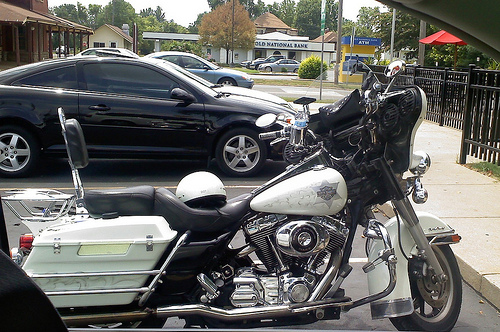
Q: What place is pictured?
A: It is a parking lot.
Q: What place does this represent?
A: It represents the parking lot.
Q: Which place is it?
A: It is a parking lot.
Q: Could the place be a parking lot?
A: Yes, it is a parking lot.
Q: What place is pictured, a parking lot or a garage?
A: It is a parking lot.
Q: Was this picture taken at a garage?
A: No, the picture was taken in a parking lot.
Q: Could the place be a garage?
A: No, it is a parking lot.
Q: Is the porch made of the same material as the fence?
A: No, the porch is made of wood and the fence is made of metal.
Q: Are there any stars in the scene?
A: Yes, there is a star.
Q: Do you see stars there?
A: Yes, there is a star.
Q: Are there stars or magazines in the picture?
A: Yes, there is a star.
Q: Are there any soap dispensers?
A: No, there are no soap dispensers.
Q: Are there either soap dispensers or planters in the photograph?
A: No, there are no soap dispensers or planters.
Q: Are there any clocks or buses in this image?
A: No, there are no buses or clocks.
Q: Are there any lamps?
A: No, there are no lamps.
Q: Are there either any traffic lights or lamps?
A: No, there are no lamps or traffic lights.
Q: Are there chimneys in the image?
A: No, there are no chimneys.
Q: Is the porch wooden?
A: Yes, the porch is wooden.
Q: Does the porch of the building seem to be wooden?
A: Yes, the porch is wooden.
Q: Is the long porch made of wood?
A: Yes, the porch is made of wood.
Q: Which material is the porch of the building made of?
A: The porch is made of wood.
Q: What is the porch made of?
A: The porch is made of wood.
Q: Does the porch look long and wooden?
A: Yes, the porch is long and wooden.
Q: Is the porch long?
A: Yes, the porch is long.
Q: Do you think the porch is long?
A: Yes, the porch is long.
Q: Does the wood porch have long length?
A: Yes, the porch is long.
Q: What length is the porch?
A: The porch is long.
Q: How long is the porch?
A: The porch is long.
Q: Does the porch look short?
A: No, the porch is long.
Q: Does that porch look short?
A: No, the porch is long.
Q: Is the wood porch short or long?
A: The porch is long.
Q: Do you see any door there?
A: Yes, there is a door.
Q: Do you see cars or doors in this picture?
A: Yes, there is a door.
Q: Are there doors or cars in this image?
A: Yes, there is a door.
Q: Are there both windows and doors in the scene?
A: Yes, there are both a door and a window.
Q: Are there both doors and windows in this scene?
A: Yes, there are both a door and a window.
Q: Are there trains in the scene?
A: No, there are no trains.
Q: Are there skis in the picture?
A: No, there are no skis.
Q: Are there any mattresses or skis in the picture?
A: No, there are no skis or mattresses.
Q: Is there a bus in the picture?
A: No, there are no buses.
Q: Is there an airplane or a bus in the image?
A: No, there are no buses or airplanes.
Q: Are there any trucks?
A: No, there are no trucks.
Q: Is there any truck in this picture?
A: No, there are no trucks.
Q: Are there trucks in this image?
A: No, there are no trucks.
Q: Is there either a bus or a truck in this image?
A: No, there are no trucks or buses.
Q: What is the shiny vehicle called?
A: The vehicle is a car.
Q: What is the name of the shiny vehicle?
A: The vehicle is a car.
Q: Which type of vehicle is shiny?
A: The vehicle is a car.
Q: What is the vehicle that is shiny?
A: The vehicle is a car.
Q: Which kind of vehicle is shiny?
A: The vehicle is a car.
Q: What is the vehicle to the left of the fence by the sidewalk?
A: The vehicle is a car.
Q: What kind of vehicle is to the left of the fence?
A: The vehicle is a car.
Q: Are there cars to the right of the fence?
A: No, the car is to the left of the fence.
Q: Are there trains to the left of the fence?
A: No, there is a car to the left of the fence.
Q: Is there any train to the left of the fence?
A: No, there is a car to the left of the fence.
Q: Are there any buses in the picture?
A: No, there are no buses.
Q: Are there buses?
A: No, there are no buses.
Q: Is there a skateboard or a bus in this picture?
A: No, there are no buses or skateboards.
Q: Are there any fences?
A: Yes, there is a fence.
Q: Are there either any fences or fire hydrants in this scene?
A: Yes, there is a fence.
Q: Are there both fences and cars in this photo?
A: Yes, there are both a fence and a car.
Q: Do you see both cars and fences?
A: Yes, there are both a fence and a car.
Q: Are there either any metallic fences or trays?
A: Yes, there is a metal fence.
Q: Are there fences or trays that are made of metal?
A: Yes, the fence is made of metal.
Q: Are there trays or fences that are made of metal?
A: Yes, the fence is made of metal.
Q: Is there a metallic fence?
A: Yes, there is a metal fence.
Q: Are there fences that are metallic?
A: Yes, there is a fence that is metallic.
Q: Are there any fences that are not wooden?
A: Yes, there is a metallic fence.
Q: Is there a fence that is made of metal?
A: Yes, there is a fence that is made of metal.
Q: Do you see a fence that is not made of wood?
A: Yes, there is a fence that is made of metal.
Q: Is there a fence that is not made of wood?
A: Yes, there is a fence that is made of metal.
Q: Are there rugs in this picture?
A: No, there are no rugs.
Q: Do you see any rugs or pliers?
A: No, there are no rugs or pliers.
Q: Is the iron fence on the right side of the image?
A: Yes, the fence is on the right of the image.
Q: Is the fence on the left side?
A: No, the fence is on the right of the image.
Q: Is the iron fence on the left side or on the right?
A: The fence is on the right of the image.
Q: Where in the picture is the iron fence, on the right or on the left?
A: The fence is on the right of the image.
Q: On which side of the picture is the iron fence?
A: The fence is on the right of the image.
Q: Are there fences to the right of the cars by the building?
A: Yes, there is a fence to the right of the cars.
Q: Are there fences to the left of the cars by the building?
A: No, the fence is to the right of the cars.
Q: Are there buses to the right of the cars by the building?
A: No, there is a fence to the right of the cars.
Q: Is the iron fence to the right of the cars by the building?
A: Yes, the fence is to the right of the cars.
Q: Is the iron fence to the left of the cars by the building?
A: No, the fence is to the right of the cars.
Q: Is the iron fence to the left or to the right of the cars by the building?
A: The fence is to the right of the cars.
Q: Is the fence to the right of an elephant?
A: No, the fence is to the right of the car.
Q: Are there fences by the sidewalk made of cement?
A: Yes, there is a fence by the sidewalk.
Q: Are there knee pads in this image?
A: No, there are no knee pads.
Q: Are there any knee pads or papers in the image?
A: No, there are no knee pads or papers.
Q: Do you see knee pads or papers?
A: No, there are no knee pads or papers.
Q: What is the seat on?
A: The seat is on the motorbike.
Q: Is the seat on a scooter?
A: No, the seat is on the motorbike.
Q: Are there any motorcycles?
A: Yes, there is a motorcycle.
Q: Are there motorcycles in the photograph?
A: Yes, there is a motorcycle.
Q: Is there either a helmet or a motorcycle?
A: Yes, there is a motorcycle.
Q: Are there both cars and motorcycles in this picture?
A: Yes, there are both a motorcycle and a car.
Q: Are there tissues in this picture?
A: No, there are no tissues.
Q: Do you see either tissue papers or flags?
A: No, there are no tissue papers or flags.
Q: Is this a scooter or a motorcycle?
A: This is a motorcycle.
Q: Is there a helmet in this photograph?
A: Yes, there is a helmet.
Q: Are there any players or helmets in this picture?
A: Yes, there is a helmet.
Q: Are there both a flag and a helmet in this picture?
A: No, there is a helmet but no flags.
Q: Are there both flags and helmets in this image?
A: No, there is a helmet but no flags.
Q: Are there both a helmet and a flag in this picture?
A: No, there is a helmet but no flags.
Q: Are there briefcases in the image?
A: No, there are no briefcases.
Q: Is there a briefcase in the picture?
A: No, there are no briefcases.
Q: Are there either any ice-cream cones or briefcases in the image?
A: No, there are no briefcases or ice-cream cones.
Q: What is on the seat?
A: The helmet is on the seat.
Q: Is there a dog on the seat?
A: No, there is a helmet on the seat.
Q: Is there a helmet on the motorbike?
A: Yes, there is a helmet on the motorbike.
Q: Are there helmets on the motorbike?
A: Yes, there is a helmet on the motorbike.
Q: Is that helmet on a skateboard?
A: No, the helmet is on the motorcycle.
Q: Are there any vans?
A: No, there are no vans.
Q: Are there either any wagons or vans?
A: No, there are no vans or wagons.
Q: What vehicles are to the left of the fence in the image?
A: The vehicles are cars.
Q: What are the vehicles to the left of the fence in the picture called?
A: The vehicles are cars.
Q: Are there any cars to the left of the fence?
A: Yes, there are cars to the left of the fence.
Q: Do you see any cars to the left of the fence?
A: Yes, there are cars to the left of the fence.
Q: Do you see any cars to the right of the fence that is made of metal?
A: No, the cars are to the left of the fence.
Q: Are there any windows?
A: Yes, there is a window.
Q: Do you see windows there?
A: Yes, there is a window.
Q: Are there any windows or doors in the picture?
A: Yes, there is a window.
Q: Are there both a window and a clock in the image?
A: No, there is a window but no clocks.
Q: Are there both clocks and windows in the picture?
A: No, there is a window but no clocks.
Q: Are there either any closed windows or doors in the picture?
A: Yes, there is a closed window.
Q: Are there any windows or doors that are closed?
A: Yes, the window is closed.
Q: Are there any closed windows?
A: Yes, there is a closed window.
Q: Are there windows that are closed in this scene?
A: Yes, there is a closed window.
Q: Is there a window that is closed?
A: Yes, there is a window that is closed.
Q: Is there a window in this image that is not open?
A: Yes, there is an closed window.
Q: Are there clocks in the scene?
A: No, there are no clocks.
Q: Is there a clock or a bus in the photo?
A: No, there are no clocks or buses.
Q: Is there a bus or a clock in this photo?
A: No, there are no clocks or buses.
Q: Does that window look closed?
A: Yes, the window is closed.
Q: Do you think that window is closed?
A: Yes, the window is closed.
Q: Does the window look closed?
A: Yes, the window is closed.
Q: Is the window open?
A: No, the window is closed.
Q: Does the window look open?
A: No, the window is closed.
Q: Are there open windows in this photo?
A: No, there is a window but it is closed.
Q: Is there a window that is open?
A: No, there is a window but it is closed.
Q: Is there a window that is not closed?
A: No, there is a window but it is closed.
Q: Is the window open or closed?
A: The window is closed.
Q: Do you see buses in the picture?
A: No, there are no buses.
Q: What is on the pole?
A: The sign is on the pole.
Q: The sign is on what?
A: The sign is on the pole.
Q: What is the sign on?
A: The sign is on the pole.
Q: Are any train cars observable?
A: No, there are no train cars.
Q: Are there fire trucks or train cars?
A: No, there are no train cars or fire trucks.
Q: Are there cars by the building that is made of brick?
A: Yes, there are cars by the building.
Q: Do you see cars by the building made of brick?
A: Yes, there are cars by the building.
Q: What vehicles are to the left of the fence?
A: The vehicles are cars.